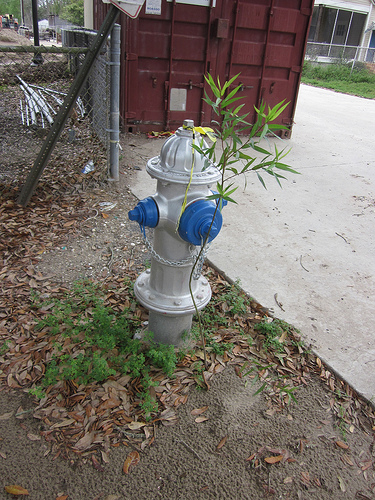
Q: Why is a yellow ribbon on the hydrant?
A: A boy tied it there.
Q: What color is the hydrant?
A: White and blue.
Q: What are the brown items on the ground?
A: Dead leaves.